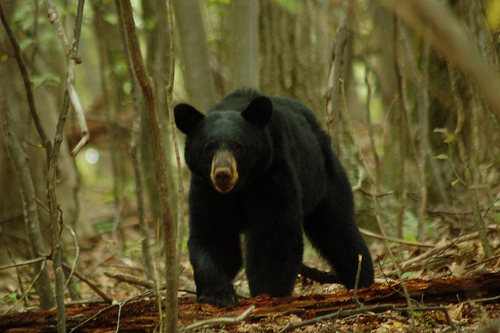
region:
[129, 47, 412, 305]
the bear is black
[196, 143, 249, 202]
bear's nose is brown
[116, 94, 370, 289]
big black bear walking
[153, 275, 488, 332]
brown twigs on the ground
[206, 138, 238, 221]
nose is brown on bear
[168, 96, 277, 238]
bear is facing camera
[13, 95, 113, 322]
high weeds in the field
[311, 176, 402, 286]
bear's hind leg is black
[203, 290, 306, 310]
two front paws on the twigs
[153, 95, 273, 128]
ears of the bear are up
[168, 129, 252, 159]
bear's eyes are black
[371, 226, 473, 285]
crushed leaves on the ground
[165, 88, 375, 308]
a big black bear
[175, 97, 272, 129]
the two ears of the bear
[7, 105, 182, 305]
some stems trees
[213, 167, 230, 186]
the nose of the bear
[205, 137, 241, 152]
two small bear eyes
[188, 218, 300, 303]
the two frontal bear legs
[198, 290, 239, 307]
long curved claws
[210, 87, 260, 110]
the bear shoulder muscle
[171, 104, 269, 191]
bear big head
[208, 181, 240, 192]
bear closed mouth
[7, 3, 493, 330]
Black bear walking in the woods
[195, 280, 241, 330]
Bear's paw on dead tree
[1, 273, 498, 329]
Rotten log laying on ground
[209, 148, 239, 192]
Brown patch on bear's snout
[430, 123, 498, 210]
Leaves growing on tree branch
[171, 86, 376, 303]
Black bear facing forward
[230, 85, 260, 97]
Fur standing up on bear's back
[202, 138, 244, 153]
Brown eyes on bear's face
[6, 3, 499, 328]
Forest growing behind bear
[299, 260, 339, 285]
Branch under black bear